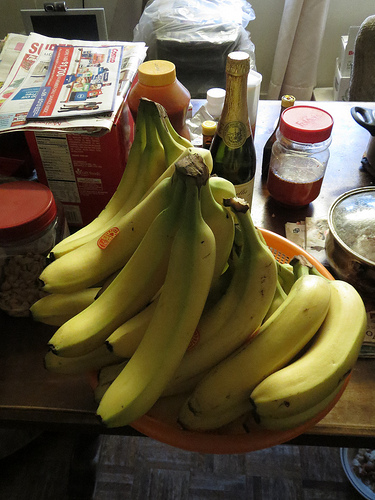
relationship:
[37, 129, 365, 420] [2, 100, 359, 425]
bananas on table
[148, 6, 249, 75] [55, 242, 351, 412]
sack behind table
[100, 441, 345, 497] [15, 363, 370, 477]
floor under table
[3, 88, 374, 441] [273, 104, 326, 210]
table holding item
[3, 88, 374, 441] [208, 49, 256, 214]
table holding bottle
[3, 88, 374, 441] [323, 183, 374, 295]
table holding pot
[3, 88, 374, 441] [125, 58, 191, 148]
table holding bottle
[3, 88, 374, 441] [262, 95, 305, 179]
table holding item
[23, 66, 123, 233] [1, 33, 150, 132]
box under newspaper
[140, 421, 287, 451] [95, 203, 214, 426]
bowl under banana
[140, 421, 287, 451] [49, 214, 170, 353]
bowl under banana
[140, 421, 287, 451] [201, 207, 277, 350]
bowl under banana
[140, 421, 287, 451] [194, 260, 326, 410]
bowl under banana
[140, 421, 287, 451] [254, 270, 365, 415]
bowl under banana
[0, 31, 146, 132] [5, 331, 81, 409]
news papers on table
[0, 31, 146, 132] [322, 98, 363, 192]
news papers on table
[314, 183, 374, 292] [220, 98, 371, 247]
pot on table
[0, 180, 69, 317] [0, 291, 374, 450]
plastic container on table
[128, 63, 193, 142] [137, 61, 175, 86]
bottle has lid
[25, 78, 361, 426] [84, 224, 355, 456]
bananas in basket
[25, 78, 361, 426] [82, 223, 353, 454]
bananas overflowing bowl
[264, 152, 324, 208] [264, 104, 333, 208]
liquid inside item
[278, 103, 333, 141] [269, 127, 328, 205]
cap on jar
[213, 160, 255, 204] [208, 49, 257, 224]
champagne in bottle